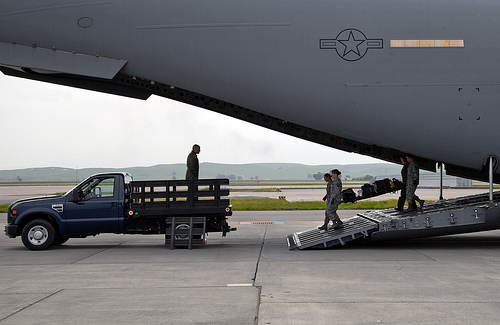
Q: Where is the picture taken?
A: Airport.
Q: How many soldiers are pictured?
A: 5.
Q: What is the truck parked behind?
A: Airplane.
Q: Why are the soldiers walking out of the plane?
A: Unloading.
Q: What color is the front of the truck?
A: Blue.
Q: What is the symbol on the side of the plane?
A: Star.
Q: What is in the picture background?
A: Mountains.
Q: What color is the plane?
A: Grey.